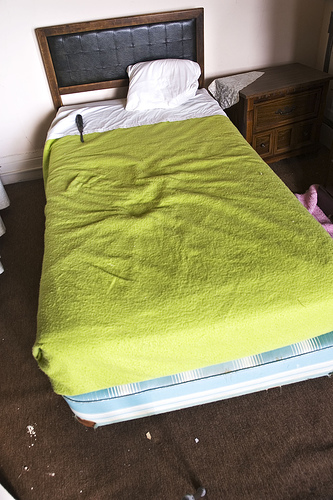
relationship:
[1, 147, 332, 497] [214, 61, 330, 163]
carpet beside cabinet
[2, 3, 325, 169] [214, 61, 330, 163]
wall near cabinet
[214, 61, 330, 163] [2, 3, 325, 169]
cabinet near wall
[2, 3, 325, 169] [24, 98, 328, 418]
wall near bed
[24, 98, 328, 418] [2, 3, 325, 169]
bed near wall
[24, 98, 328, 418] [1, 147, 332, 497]
bed on carpet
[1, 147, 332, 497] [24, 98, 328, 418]
carpet under bed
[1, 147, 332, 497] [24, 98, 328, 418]
carpet below bed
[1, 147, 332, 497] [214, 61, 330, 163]
carpet below cabinet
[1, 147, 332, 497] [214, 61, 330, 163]
carpet under cabinet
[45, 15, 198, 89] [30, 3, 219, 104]
cushion on headboard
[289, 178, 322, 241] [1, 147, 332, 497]
clothing on carpet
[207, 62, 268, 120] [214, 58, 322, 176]
clothing on desk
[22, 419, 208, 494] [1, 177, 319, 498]
debris on carpet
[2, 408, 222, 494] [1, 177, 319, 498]
debris on carpet